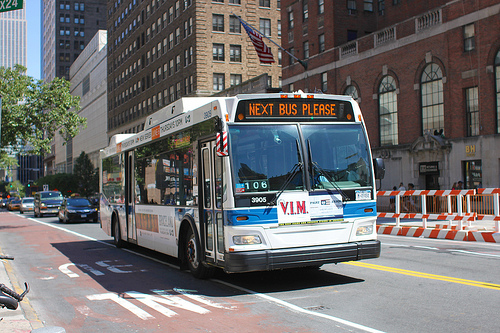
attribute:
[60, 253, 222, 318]
letters — white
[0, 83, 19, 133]
leaves — green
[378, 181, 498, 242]
barriers — orange and white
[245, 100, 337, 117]
text — orange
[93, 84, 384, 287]
bus — blue and white, white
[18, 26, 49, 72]
sky — shiny, blue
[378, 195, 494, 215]
border — red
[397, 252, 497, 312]
line — yellow